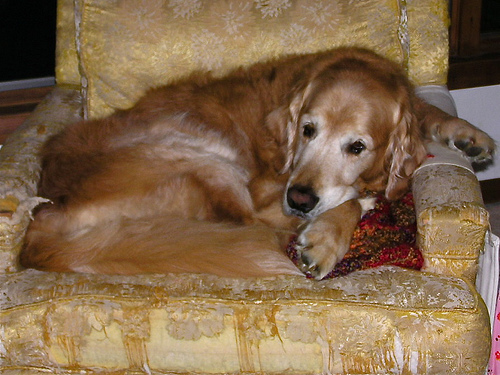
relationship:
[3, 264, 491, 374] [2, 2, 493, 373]
cushion on arm chair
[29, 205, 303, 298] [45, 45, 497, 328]
tail on dog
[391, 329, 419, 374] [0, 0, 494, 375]
tear in cushon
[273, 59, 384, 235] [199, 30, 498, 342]
head of a dog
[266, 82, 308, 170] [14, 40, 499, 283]
ear of a dog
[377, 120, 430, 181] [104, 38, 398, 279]
ear of a dog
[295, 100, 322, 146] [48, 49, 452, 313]
eye of a dog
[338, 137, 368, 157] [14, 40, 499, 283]
eye of a dog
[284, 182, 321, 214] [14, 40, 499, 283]
nose of a dog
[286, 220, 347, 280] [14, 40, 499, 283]
paw of a dog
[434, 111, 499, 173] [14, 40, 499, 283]
paw of a dog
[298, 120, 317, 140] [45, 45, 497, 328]
eye of a dog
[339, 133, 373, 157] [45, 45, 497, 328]
eye of a dog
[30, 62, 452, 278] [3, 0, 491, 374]
dog seated on arm chair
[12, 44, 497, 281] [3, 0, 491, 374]
dog in arm chair